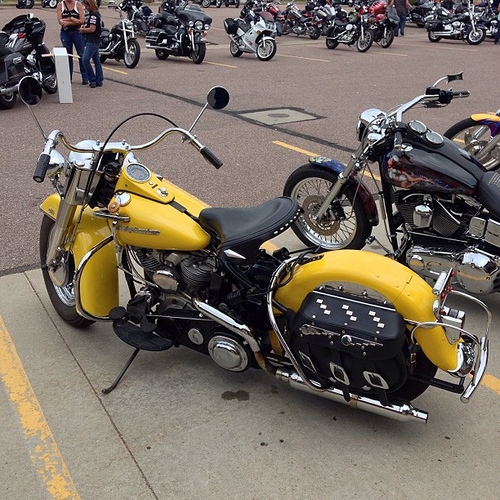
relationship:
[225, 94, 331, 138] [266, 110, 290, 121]
cement with grate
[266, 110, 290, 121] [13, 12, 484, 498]
grate in lot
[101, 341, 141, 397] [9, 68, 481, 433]
stand on bike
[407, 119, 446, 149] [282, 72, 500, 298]
gauges on bike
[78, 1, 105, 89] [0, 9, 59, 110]
woman observing bikes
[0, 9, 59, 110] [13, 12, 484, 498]
bikes in lot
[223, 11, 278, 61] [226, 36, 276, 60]
bike with tires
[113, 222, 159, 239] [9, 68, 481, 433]
logo on bike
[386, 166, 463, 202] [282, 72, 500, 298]
design on bike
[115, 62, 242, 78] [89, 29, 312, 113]
lines on ground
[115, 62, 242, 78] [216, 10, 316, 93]
lines for parking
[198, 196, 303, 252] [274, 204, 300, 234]
seat with studs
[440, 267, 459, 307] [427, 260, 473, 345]
lights on back of piece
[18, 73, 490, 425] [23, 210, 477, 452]
bike in space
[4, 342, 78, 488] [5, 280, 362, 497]
line in space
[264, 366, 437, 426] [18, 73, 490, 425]
tailpipe on bike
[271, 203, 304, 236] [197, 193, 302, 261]
studs on back of seat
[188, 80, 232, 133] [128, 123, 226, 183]
mirror on handlebar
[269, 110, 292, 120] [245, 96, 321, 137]
top on surface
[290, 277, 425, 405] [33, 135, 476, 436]
case on side of motorcycle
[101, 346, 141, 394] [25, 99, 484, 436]
stand on side of motorcycle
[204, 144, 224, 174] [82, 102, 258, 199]
black tip of handlebars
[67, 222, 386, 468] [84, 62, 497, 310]
lot with motorized bikes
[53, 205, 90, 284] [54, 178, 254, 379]
front tire on motorized bike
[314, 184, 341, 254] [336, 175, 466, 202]
front tire on motorized bike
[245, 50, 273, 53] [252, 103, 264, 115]
motorized bike on lot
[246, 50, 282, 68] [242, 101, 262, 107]
front tire on motorized bike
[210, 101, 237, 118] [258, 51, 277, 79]
rear tire on motorized bike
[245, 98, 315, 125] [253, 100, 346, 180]
covering on lot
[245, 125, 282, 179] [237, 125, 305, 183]
tar in lot crevice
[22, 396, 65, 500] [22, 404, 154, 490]
strip separating lanes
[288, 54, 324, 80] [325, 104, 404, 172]
empty spot with no bike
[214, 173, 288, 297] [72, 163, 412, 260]
seat of motorbike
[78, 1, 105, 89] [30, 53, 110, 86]
woman standing beside bikes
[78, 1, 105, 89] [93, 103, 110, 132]
woman dressed in jeans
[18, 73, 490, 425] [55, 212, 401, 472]
bike put on display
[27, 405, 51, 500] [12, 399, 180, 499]
mark on parking lot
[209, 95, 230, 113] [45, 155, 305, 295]
round side mirror of bike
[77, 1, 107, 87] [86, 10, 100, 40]
woman in t-shirt